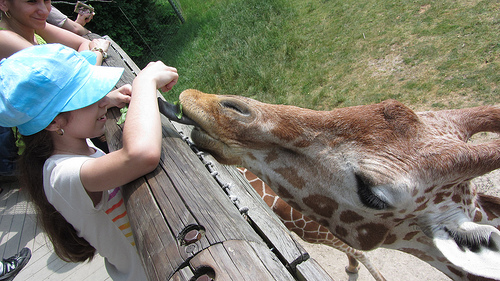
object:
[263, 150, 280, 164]
spot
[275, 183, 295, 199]
spot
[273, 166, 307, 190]
spot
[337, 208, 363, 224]
spot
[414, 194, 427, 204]
spot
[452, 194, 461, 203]
spot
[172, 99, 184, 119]
leaf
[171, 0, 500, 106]
grass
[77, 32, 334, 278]
fence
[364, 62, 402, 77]
dirt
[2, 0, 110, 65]
person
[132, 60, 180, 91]
hand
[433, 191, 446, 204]
spot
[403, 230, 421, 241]
spot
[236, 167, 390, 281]
giraffe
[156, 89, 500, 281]
giraffe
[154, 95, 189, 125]
tongue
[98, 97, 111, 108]
nose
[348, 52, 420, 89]
bare earth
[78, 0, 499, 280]
exhibit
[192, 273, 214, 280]
bolt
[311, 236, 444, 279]
ground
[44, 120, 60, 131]
ear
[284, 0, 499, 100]
patch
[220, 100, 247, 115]
nostril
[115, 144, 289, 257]
wood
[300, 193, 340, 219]
spot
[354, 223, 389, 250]
spot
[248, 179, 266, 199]
spot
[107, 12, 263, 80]
trees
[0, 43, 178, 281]
girl